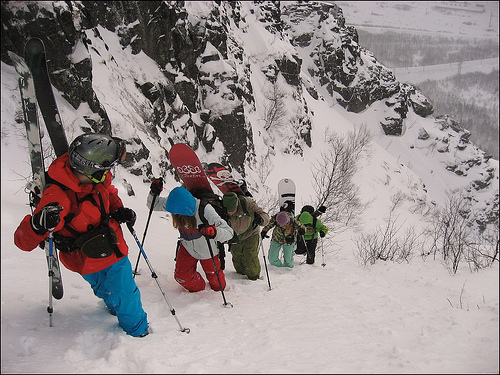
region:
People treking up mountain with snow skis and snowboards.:
[14, 113, 356, 350]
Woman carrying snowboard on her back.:
[148, 140, 235, 298]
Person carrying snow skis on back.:
[12, 41, 91, 303]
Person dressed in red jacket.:
[9, 147, 136, 270]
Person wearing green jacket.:
[297, 211, 332, 243]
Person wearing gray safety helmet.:
[66, 128, 128, 177]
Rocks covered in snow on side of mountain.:
[296, 2, 484, 192]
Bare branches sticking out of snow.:
[358, 187, 498, 269]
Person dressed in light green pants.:
[266, 238, 305, 270]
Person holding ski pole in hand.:
[256, 230, 279, 305]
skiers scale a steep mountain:
[13, 122, 424, 338]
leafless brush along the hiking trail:
[319, 111, 496, 280]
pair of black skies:
[6, 21, 71, 338]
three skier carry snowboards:
[160, 130, 299, 295]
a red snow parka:
[11, 149, 131, 274]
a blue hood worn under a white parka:
[151, 186, 231, 254]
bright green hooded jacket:
[293, 209, 327, 244]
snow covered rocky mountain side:
[253, 1, 486, 219]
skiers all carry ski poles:
[118, 214, 335, 330]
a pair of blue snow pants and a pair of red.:
[76, 251, 250, 333]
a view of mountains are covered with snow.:
[182, 30, 387, 131]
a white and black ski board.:
[271, 175, 296, 205]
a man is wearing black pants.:
[296, 240, 321, 260]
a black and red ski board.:
[200, 151, 245, 191]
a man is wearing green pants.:
[226, 236, 266, 276]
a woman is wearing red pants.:
[170, 250, 237, 290]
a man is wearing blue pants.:
[80, 275, 152, 330]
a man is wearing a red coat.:
[56, 187, 131, 257]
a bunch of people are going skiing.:
[10, 66, 365, 333]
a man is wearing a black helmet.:
[65, 130, 120, 175]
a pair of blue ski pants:
[78, 256, 165, 348]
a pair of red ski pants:
[147, 240, 232, 317]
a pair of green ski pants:
[223, 234, 278, 296]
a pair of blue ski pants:
[258, 238, 297, 280]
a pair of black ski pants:
[288, 236, 325, 274]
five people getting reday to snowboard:
[2, 158, 347, 321]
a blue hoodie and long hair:
[155, 184, 200, 227]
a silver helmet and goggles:
[76, 123, 139, 177]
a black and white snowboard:
[251, 165, 313, 220]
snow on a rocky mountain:
[345, 100, 477, 205]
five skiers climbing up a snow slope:
[9, 67, 354, 337]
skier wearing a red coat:
[16, 60, 161, 347]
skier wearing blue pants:
[11, 70, 166, 343]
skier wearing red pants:
[141, 137, 229, 307]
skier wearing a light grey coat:
[143, 172, 243, 314]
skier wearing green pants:
[213, 170, 278, 296]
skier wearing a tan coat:
[211, 162, 281, 289]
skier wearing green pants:
[256, 183, 308, 283]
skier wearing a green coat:
[292, 196, 334, 275]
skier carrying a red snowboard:
[163, 125, 231, 295]